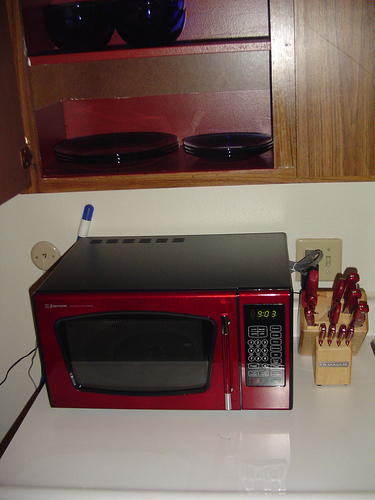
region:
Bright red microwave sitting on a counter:
[25, 238, 308, 435]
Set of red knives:
[299, 259, 370, 405]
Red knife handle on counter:
[301, 267, 327, 304]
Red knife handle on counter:
[302, 293, 320, 315]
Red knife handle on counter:
[299, 303, 318, 333]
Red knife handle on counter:
[313, 312, 325, 363]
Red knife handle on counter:
[328, 319, 333, 359]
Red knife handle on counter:
[336, 319, 344, 352]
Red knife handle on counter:
[346, 318, 354, 352]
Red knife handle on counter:
[345, 300, 373, 341]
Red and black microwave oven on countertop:
[29, 231, 294, 412]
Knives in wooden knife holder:
[298, 265, 370, 385]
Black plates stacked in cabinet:
[39, 126, 272, 172]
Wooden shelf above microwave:
[26, 0, 277, 189]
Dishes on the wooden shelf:
[17, 0, 189, 50]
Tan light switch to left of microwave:
[295, 235, 344, 280]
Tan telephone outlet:
[27, 241, 59, 269]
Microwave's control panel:
[242, 301, 285, 391]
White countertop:
[0, 334, 374, 498]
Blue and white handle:
[76, 202, 94, 235]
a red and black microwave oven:
[30, 231, 293, 411]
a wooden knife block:
[314, 335, 351, 386]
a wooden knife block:
[300, 289, 367, 357]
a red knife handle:
[318, 322, 326, 346]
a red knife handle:
[327, 323, 334, 345]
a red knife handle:
[335, 325, 345, 346]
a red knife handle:
[345, 324, 354, 345]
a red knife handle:
[302, 308, 316, 327]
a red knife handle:
[305, 292, 317, 311]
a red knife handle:
[328, 301, 341, 326]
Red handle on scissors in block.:
[328, 283, 345, 324]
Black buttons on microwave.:
[248, 337, 277, 382]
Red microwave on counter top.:
[30, 261, 241, 442]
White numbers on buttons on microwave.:
[245, 335, 289, 375]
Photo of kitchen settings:
[2, 8, 372, 491]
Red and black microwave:
[24, 271, 294, 416]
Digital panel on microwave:
[238, 301, 292, 390]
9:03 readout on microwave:
[247, 307, 283, 323]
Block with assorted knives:
[295, 262, 371, 394]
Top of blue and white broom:
[59, 201, 104, 240]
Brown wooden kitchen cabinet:
[13, 4, 373, 180]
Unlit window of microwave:
[46, 310, 223, 396]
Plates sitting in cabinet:
[42, 99, 275, 171]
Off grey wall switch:
[298, 226, 341, 283]